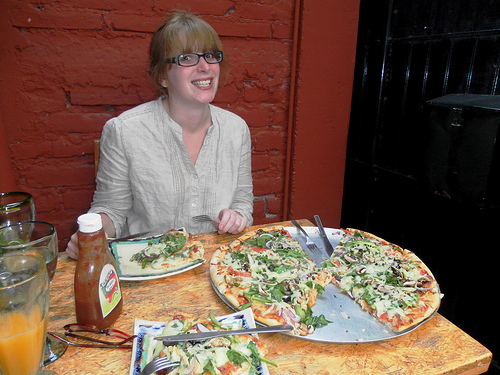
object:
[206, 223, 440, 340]
pizza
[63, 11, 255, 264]
lady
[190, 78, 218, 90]
mouth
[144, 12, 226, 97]
hair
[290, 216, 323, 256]
fork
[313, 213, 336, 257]
knife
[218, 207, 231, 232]
fingers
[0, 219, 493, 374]
table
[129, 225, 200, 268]
pizza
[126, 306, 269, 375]
plate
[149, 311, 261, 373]
pizza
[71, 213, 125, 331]
bottle of sauce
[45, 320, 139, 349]
eye glasses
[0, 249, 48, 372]
glass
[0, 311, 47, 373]
orange juice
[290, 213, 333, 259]
fork and knife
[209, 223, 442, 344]
pizza tray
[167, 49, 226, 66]
eye glasses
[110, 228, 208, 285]
plate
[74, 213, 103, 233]
top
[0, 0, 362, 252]
wall